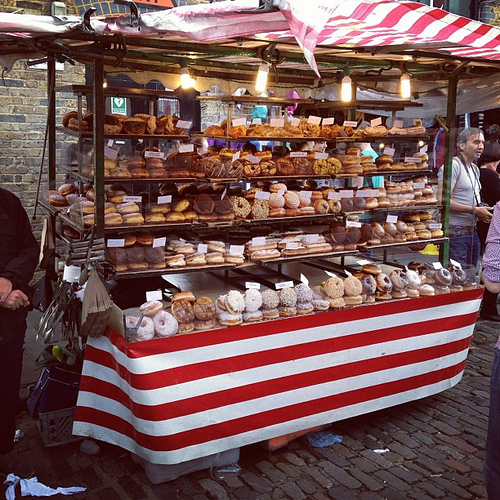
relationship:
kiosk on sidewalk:
[39, 4, 481, 485] [3, 273, 495, 494]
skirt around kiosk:
[74, 284, 484, 466] [39, 4, 481, 485]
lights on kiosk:
[173, 61, 418, 105] [39, 4, 481, 485]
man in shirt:
[438, 125, 495, 284] [434, 158, 484, 236]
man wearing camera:
[438, 125, 495, 284] [477, 201, 493, 220]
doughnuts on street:
[189, 195, 236, 222] [0, 261, 494, 500]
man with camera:
[438, 125, 495, 284] [477, 201, 493, 220]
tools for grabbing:
[34, 230, 99, 347] [34, 230, 97, 339]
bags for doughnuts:
[78, 269, 114, 339] [189, 195, 236, 222]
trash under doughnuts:
[307, 431, 340, 448] [189, 195, 236, 222]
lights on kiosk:
[173, 61, 418, 105] [39, 4, 500, 484]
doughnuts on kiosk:
[189, 195, 236, 222] [39, 4, 500, 484]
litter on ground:
[22, 479, 51, 496] [0, 413, 432, 500]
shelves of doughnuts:
[100, 113, 451, 277] [189, 195, 236, 222]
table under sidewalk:
[85, 255, 476, 340] [3, 273, 495, 494]